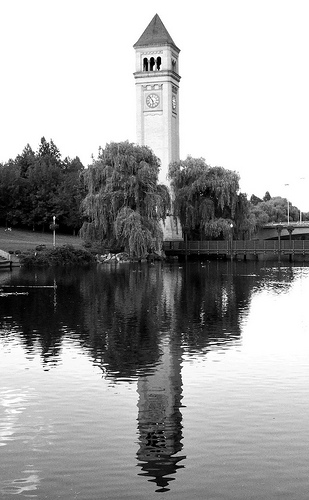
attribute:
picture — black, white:
[2, 2, 284, 454]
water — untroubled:
[196, 345, 234, 398]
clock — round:
[144, 92, 162, 113]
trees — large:
[90, 138, 162, 248]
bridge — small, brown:
[260, 217, 309, 238]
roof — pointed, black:
[135, 7, 183, 49]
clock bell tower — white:
[122, 11, 191, 111]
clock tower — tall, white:
[126, 6, 193, 242]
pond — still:
[22, 423, 79, 500]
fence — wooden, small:
[2, 257, 14, 271]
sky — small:
[220, 14, 302, 65]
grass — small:
[22, 231, 44, 241]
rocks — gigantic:
[95, 252, 132, 266]